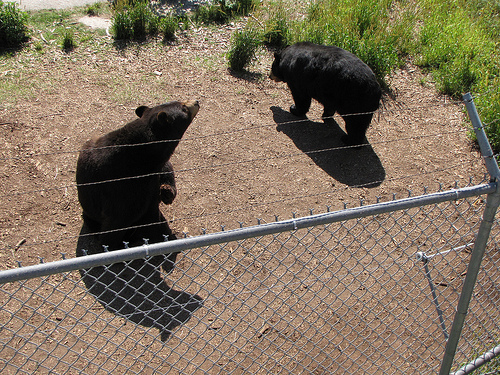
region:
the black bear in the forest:
[261, 21, 403, 154]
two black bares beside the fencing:
[68, 6, 393, 231]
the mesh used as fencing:
[232, 271, 417, 346]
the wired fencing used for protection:
[125, 132, 287, 211]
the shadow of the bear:
[67, 247, 252, 328]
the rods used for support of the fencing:
[447, 221, 477, 362]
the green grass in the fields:
[411, 5, 477, 60]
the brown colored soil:
[208, 142, 275, 202]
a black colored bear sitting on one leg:
[73, 77, 188, 264]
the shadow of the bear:
[265, 88, 396, 190]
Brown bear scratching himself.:
[68, 92, 203, 234]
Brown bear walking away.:
[256, 36, 388, 143]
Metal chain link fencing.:
[3, 238, 493, 371]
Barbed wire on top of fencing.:
[0, 142, 470, 237]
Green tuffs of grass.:
[97, 6, 193, 46]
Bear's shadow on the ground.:
[260, 106, 386, 187]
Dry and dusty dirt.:
[15, 80, 66, 228]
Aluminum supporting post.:
[453, 92, 498, 363]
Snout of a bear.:
[178, 95, 201, 117]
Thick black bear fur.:
[289, 44, 371, 111]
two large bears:
[95, 29, 412, 248]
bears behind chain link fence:
[68, 16, 444, 341]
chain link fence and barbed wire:
[227, 86, 492, 280]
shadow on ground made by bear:
[288, 132, 386, 212]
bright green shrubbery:
[368, 8, 465, 69]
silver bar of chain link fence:
[57, 200, 475, 285]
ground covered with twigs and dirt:
[42, 66, 127, 123]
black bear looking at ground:
[256, 28, 393, 152]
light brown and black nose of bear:
[177, 92, 206, 120]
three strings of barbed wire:
[202, 112, 303, 223]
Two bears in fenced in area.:
[39, 32, 407, 362]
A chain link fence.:
[9, 230, 454, 368]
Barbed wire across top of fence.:
[11, 145, 391, 260]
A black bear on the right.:
[264, 37, 401, 148]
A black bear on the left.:
[68, 68, 198, 228]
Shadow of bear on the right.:
[255, 115, 392, 195]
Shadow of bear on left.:
[73, 207, 203, 342]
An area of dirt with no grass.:
[30, 92, 439, 357]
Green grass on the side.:
[393, 10, 499, 87]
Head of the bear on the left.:
[120, 90, 215, 153]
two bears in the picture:
[43, 32, 471, 208]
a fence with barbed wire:
[199, 126, 494, 278]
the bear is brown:
[66, 108, 256, 218]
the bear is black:
[267, 46, 479, 143]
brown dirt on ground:
[226, 134, 497, 290]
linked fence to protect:
[226, 264, 456, 354]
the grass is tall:
[433, 11, 494, 86]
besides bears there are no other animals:
[18, 21, 448, 246]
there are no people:
[8, 13, 400, 345]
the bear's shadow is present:
[51, 218, 253, 360]